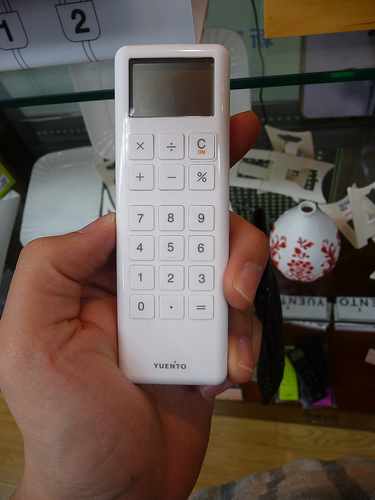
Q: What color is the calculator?
A: White.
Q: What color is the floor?
A: Brown.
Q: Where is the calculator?
A: In the hand.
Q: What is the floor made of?
A: Wood.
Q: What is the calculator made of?
A: Plastic.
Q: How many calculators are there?
A: One.